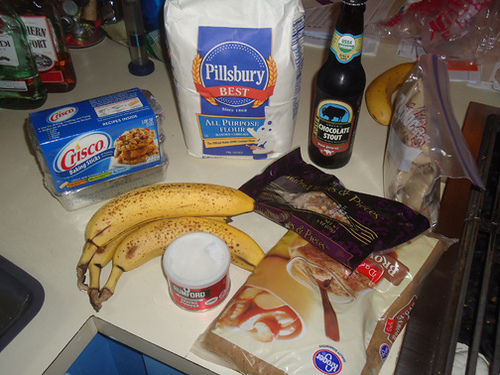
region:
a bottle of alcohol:
[282, 0, 382, 187]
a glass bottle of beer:
[292, 0, 374, 174]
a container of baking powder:
[135, 223, 290, 367]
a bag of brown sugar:
[226, 223, 431, 373]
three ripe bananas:
[18, 170, 311, 299]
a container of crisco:
[8, 87, 205, 224]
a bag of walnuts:
[218, 134, 442, 294]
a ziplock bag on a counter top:
[375, 26, 495, 280]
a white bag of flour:
[147, 2, 354, 220]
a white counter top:
[52, 83, 497, 357]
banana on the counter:
[76, 189, 266, 309]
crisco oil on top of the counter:
[23, 88, 185, 198]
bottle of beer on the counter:
[315, 12, 362, 189]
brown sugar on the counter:
[190, 203, 473, 330]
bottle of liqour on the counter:
[8, 1, 56, 111]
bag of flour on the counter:
[177, 25, 292, 156]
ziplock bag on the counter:
[381, 56, 461, 226]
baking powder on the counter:
[146, 241, 239, 316]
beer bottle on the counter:
[311, 32, 364, 178]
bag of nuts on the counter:
[255, 134, 412, 264]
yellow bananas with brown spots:
[73, 180, 265, 315]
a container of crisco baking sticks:
[21, 85, 171, 214]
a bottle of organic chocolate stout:
[305, 0, 367, 172]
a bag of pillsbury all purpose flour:
[157, 2, 300, 166]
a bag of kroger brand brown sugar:
[192, 227, 461, 372]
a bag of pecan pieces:
[235, 139, 435, 273]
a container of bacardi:
[2, 1, 48, 112]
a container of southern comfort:
[1, 2, 79, 97]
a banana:
[363, 44, 420, 138]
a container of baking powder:
[157, 227, 237, 316]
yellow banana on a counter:
[69, 178, 266, 311]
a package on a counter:
[30, 86, 167, 208]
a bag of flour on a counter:
[167, 1, 304, 160]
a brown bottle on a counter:
[305, 1, 369, 164]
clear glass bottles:
[3, 0, 74, 115]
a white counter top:
[0, 201, 58, 252]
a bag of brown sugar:
[208, 228, 455, 373]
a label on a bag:
[191, 26, 275, 154]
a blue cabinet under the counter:
[72, 339, 174, 374]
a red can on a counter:
[158, 237, 228, 315]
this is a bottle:
[313, 2, 373, 143]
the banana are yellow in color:
[114, 199, 178, 252]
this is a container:
[171, 237, 223, 304]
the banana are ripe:
[98, 195, 168, 252]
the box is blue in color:
[49, 97, 158, 170]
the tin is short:
[172, 237, 237, 304]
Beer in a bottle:
[313, 4, 362, 165]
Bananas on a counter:
[68, 182, 264, 307]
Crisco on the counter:
[16, 119, 173, 195]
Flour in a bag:
[157, 4, 300, 170]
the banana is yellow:
[72, 183, 255, 270]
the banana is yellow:
[91, 216, 231, 260]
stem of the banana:
[101, 267, 119, 303]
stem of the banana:
[89, 266, 102, 304]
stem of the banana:
[73, 246, 97, 288]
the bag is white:
[171, 19, 188, 52]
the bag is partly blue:
[205, 26, 268, 47]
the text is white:
[207, 64, 264, 83]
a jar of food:
[162, 233, 236, 315]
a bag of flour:
[164, 0, 299, 161]